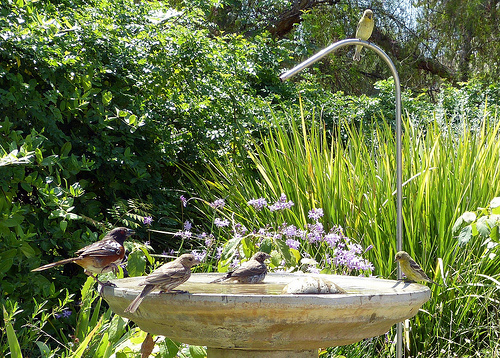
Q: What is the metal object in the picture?
A: A faucet.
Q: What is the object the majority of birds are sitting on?
A: A bird bath.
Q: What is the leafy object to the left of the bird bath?
A: A bush.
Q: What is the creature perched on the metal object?
A: A bird.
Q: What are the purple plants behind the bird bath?
A: Flowers.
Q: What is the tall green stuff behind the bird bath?
A: A plant.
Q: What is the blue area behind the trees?
A: The sky.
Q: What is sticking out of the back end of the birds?
A: Tail feathers.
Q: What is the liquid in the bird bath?
A: Water.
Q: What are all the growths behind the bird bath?
A: Plants.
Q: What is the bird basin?
A: Stone.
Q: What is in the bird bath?
A: 4 birds.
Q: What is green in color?
A: The tall grassy plant.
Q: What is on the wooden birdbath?
A: The birds.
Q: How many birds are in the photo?
A: 4.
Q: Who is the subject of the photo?
A: The birds.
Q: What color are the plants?
A: Green.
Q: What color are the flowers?
A: Purple.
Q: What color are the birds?
A: Brown.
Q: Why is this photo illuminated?
A: Sunlight.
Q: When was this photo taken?
A: During the Day.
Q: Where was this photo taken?
A: In a garden with a bird bath.